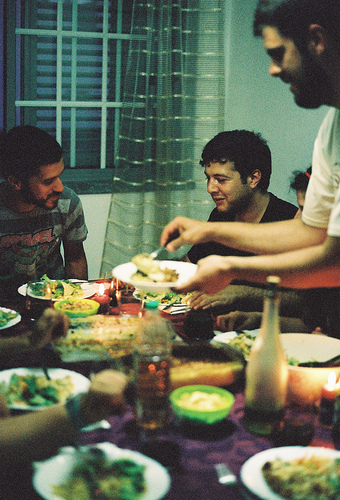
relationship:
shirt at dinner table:
[0, 184, 88, 284] [1, 278, 338, 498]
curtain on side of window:
[98, 2, 225, 278] [6, 1, 196, 192]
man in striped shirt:
[0, 123, 89, 287] [1, 185, 86, 286]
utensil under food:
[142, 247, 166, 260] [133, 250, 177, 280]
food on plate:
[133, 250, 177, 280] [175, 260, 195, 284]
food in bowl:
[177, 388, 228, 411] [169, 383, 235, 432]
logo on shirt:
[0, 227, 60, 280] [0, 204, 67, 278]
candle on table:
[84, 277, 112, 314] [17, 271, 327, 479]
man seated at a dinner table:
[181, 127, 302, 268] [1, 278, 338, 498]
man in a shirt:
[0, 123, 98, 280] [0, 184, 88, 284]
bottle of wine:
[236, 277, 292, 442] [242, 381, 287, 437]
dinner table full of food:
[1, 278, 338, 498] [166, 384, 236, 426]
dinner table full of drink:
[1, 278, 338, 498] [240, 275, 288, 431]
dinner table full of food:
[1, 278, 338, 498] [2, 367, 84, 420]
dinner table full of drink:
[1, 278, 338, 498] [133, 298, 171, 428]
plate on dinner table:
[239, 443, 339, 498] [1, 278, 338, 498]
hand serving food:
[160, 214, 208, 250] [133, 250, 177, 280]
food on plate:
[133, 250, 177, 280] [111, 256, 199, 290]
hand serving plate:
[160, 214, 208, 250] [111, 256, 199, 290]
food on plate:
[133, 250, 177, 280] [108, 262, 199, 296]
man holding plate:
[114, 12, 338, 308] [108, 262, 199, 296]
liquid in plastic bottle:
[141, 355, 173, 420] [132, 298, 172, 427]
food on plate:
[133, 250, 177, 280] [121, 256, 206, 290]